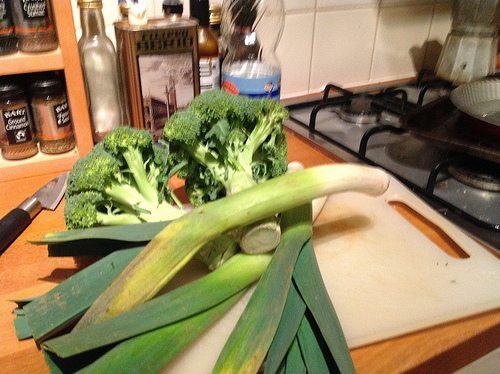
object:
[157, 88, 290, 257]
broccoli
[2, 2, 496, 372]
kitchen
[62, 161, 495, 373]
cutting board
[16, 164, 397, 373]
leek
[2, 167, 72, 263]
knife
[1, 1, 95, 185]
spice rack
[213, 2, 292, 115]
vegetable oil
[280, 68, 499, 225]
stove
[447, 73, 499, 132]
pie pan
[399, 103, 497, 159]
cookie sheet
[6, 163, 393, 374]
counter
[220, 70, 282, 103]
blue label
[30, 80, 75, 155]
spices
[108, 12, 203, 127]
olive oil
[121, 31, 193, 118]
gold can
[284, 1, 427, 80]
wall